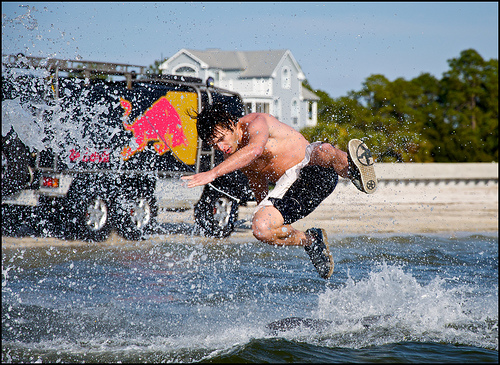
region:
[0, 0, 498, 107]
The sky is blue.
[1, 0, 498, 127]
The sky is clear.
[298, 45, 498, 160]
The trees are green.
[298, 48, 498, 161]
The trees have leaves.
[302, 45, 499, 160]
Trees are in the background.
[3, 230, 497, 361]
The water is blue.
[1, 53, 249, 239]
A truck is in the background.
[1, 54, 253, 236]
The truck is black.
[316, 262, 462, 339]
The waves are white.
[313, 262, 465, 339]
The water is splashing.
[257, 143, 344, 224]
the man is wearing shorts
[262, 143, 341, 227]
the shorts are black and white in color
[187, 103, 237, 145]
the man's hair is wet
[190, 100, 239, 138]
the man's hair is black in color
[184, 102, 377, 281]
the man is in mid air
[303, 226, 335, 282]
the man is wearing sneakers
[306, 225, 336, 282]
the sneakers are black in color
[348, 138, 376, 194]
the sole of the shoe is tan in color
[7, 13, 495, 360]
the water is splashing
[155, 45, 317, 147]
a house is in the background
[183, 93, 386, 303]
man about to fall in the water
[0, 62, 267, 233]
black van by the water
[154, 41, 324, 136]
large gray houses by the water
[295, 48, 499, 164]
trees by the gray houses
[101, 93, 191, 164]
logo of a bull on the van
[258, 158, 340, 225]
black shorts on the man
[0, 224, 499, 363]
small body of water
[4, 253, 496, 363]
waves in the water created by the man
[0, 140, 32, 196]
spare tire on the back of the van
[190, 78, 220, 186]
silver ladder on the side of the van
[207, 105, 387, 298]
A man is jumping in water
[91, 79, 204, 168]
A red bull on a car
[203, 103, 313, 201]
The man is not wearing a shirt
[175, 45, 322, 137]
A house near a beach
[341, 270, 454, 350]
A splash of a wave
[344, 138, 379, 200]
The sole of a man's shoe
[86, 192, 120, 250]
The tire of a truck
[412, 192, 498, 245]
The sand along the beach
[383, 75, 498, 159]
Green trees in the distance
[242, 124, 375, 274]
The person is wearing shorts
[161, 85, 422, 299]
man falling into water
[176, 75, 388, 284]
man jumping into the water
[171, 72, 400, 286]
man swinging into the water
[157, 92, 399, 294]
man with short dark hair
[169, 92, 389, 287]
man wearing black and white shorts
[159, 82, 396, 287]
man wearing black and tan skate shoes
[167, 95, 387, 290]
man wearing no shirt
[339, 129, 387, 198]
skate shoe with design on sole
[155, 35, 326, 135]
large light blue two story house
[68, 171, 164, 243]
two wheels for large vehicle